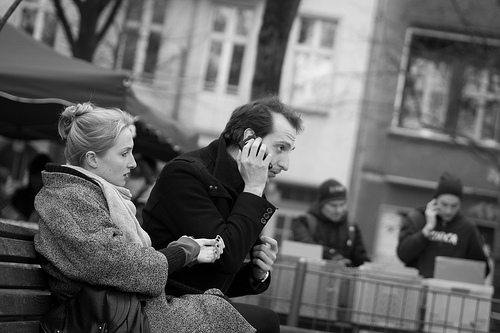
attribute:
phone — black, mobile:
[235, 131, 274, 176]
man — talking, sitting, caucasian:
[137, 94, 310, 332]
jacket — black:
[139, 133, 273, 306]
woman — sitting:
[29, 97, 260, 333]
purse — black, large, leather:
[29, 279, 153, 332]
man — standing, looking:
[392, 170, 494, 284]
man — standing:
[282, 173, 374, 270]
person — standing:
[9, 147, 58, 225]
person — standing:
[123, 144, 161, 229]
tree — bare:
[310, 1, 499, 189]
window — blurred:
[275, 7, 349, 121]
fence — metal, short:
[228, 255, 499, 332]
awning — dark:
[2, 16, 206, 169]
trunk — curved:
[246, 1, 307, 105]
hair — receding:
[217, 92, 308, 154]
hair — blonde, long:
[55, 97, 140, 168]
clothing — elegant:
[31, 155, 263, 332]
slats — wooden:
[1, 219, 53, 332]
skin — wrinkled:
[278, 124, 299, 150]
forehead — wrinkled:
[273, 115, 301, 149]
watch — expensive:
[255, 268, 272, 290]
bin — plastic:
[349, 255, 427, 332]